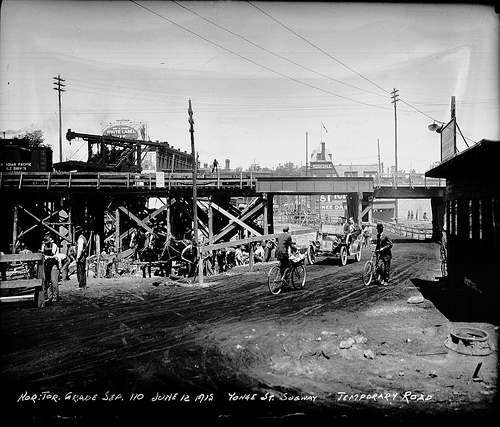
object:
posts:
[391, 82, 399, 176]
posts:
[57, 72, 64, 167]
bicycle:
[362, 249, 390, 286]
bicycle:
[267, 251, 307, 294]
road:
[5, 218, 497, 423]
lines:
[2, 2, 477, 132]